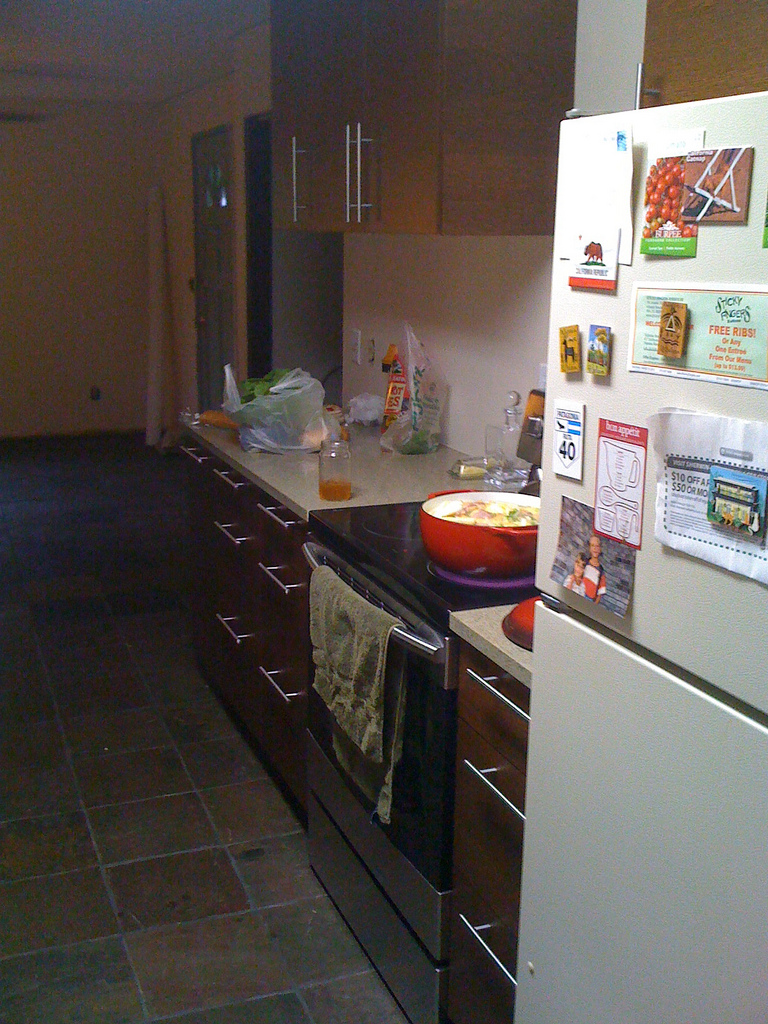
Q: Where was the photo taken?
A: The kitchen.